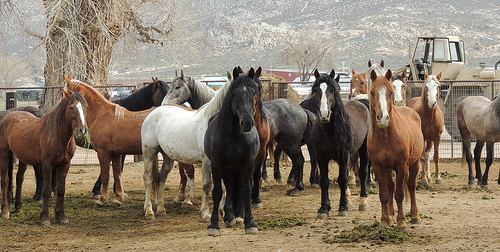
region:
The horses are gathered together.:
[0, 53, 499, 250]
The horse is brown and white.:
[355, 59, 430, 241]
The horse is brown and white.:
[407, 64, 453, 191]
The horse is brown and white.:
[0, 86, 92, 231]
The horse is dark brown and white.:
[306, 55, 372, 223]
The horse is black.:
[202, 61, 265, 242]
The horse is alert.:
[304, 61, 373, 220]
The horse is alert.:
[365, 61, 428, 230]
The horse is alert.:
[199, 55, 274, 236]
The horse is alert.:
[406, 65, 456, 195]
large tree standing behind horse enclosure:
[23, 2, 174, 117]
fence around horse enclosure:
[0, 77, 499, 165]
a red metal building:
[268, 67, 346, 81]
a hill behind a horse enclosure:
[0, 0, 498, 79]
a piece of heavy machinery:
[371, 35, 498, 143]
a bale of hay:
[259, 73, 303, 105]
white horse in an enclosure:
[140, 70, 232, 220]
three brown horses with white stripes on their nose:
[367, 70, 439, 224]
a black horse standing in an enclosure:
[203, 68, 259, 236]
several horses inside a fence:
[0, 70, 496, 249]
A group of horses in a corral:
[0, 59, 499, 237]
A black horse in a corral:
[203, 65, 261, 233]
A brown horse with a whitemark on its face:
[367, 68, 424, 228]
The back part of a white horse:
[141, 70, 233, 222]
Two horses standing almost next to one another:
[310, 69, 425, 227]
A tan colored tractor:
[390, 33, 499, 138]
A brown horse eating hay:
[0, 87, 90, 223]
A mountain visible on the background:
[0, 0, 497, 90]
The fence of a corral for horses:
[1, 79, 498, 164]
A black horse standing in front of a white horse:
[140, 65, 260, 234]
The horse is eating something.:
[1, 86, 101, 233]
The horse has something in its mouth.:
[0, 80, 103, 247]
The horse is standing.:
[1, 75, 101, 233]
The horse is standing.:
[198, 65, 270, 240]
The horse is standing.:
[357, 61, 429, 238]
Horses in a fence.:
[0, 62, 499, 245]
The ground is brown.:
[76, 220, 307, 250]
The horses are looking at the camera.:
[226, 65, 442, 147]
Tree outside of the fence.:
[37, 2, 114, 116]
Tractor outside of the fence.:
[390, 31, 497, 142]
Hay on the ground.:
[318, 215, 414, 250]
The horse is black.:
[200, 63, 272, 232]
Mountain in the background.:
[2, 0, 499, 60]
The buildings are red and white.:
[203, 68, 360, 93]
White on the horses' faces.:
[304, 73, 451, 135]